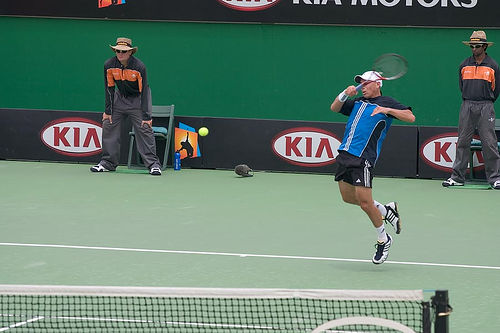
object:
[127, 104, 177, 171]
chair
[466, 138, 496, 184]
chair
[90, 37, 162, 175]
elephant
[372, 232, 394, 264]
tennis shoes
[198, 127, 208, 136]
ball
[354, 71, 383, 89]
cap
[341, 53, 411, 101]
player racquet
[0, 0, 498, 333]
court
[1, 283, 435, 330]
net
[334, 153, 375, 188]
shorts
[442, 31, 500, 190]
man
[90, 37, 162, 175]
man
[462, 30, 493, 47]
hat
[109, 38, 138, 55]
hat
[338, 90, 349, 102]
wrist band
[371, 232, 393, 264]
feet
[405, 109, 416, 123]
elbow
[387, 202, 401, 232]
foot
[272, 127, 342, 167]
logo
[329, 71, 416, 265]
athlete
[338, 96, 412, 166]
shirt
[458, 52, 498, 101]
shirt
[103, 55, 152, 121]
shirt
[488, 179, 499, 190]
foot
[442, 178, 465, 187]
foot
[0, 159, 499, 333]
ground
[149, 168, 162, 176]
foot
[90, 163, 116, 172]
foot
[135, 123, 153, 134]
knee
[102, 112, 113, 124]
hand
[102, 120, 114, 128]
knee